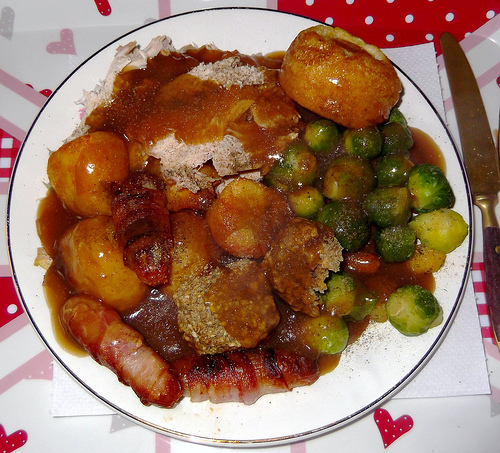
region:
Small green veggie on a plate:
[388, 287, 436, 336]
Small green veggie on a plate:
[301, 305, 343, 362]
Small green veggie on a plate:
[319, 276, 356, 325]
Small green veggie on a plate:
[413, 212, 467, 250]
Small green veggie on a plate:
[375, 227, 429, 272]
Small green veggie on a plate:
[319, 201, 365, 245]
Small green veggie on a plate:
[368, 183, 406, 227]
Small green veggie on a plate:
[318, 158, 372, 190]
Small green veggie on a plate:
[268, 143, 313, 185]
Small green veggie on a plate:
[301, 119, 338, 161]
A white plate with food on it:
[8, 4, 475, 451]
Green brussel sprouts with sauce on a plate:
[273, 108, 468, 359]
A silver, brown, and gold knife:
[438, 27, 499, 354]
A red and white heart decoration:
[368, 404, 416, 450]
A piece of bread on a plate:
[276, 22, 406, 125]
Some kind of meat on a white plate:
[71, 38, 302, 178]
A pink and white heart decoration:
[38, 28, 83, 60]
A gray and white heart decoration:
[1, 4, 18, 41]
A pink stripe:
[2, 347, 54, 396]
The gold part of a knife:
[471, 193, 498, 225]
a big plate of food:
[24, 32, 436, 439]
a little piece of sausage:
[75, 298, 175, 398]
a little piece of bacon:
[190, 344, 302, 392]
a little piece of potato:
[72, 224, 142, 303]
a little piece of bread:
[148, 87, 283, 176]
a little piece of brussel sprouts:
[333, 194, 378, 240]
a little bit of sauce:
[30, 211, 70, 248]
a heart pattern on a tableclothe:
[17, 14, 109, 59]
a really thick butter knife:
[428, 46, 495, 353]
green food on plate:
[386, 285, 445, 338]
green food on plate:
[309, 309, 375, 370]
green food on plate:
[322, 274, 359, 326]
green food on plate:
[379, 231, 419, 276]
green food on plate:
[418, 210, 465, 240]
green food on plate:
[408, 165, 448, 210]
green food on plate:
[368, 170, 419, 232]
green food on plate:
[329, 165, 365, 195]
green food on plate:
[319, 203, 377, 248]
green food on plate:
[281, 153, 316, 180]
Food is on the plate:
[69, 27, 402, 397]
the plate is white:
[55, 110, 476, 403]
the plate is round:
[6, 5, 460, 396]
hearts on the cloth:
[323, 381, 453, 446]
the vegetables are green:
[280, 132, 404, 307]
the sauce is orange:
[87, 43, 379, 383]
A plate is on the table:
[20, 8, 451, 423]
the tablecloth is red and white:
[333, 6, 457, 43]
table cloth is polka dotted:
[330, 5, 465, 50]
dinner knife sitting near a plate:
[438, 31, 498, 339]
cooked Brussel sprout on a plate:
[386, 281, 438, 336]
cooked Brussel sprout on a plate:
[409, 208, 466, 254]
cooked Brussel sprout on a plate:
[375, 225, 416, 262]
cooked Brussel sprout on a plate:
[407, 163, 455, 212]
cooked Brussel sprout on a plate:
[320, 154, 374, 202]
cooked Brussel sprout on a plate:
[288, 185, 322, 217]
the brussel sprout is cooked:
[388, 285, 443, 335]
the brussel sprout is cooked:
[410, 207, 469, 254]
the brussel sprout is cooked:
[410, 163, 455, 213]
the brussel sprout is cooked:
[323, 154, 370, 203]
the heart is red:
[373, 407, 414, 449]